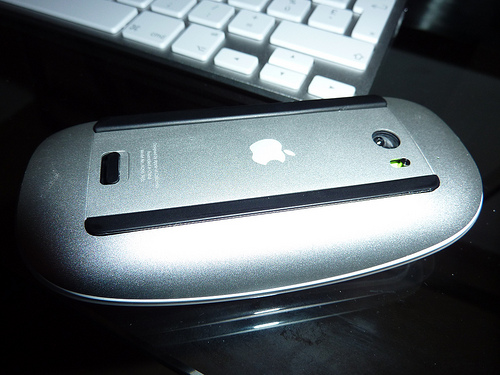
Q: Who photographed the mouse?
A: A person.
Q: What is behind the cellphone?
A: A keyboard.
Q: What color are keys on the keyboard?
A: White.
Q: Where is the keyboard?
A: Behind the cellphone.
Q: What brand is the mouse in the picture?
A: Apple.